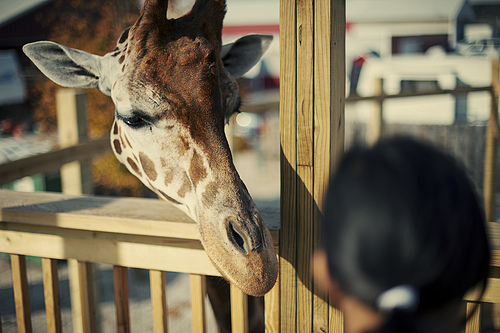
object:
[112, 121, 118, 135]
spot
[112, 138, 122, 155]
spot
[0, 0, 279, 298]
giraffe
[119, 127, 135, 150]
spot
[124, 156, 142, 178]
spot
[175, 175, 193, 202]
spot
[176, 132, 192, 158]
spot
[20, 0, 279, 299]
giraffe head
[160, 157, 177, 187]
brown spot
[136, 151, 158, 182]
brown spot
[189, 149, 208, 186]
brown spot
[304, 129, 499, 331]
person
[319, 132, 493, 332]
black hair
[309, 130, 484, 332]
person's ponytail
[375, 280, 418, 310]
ponytail holder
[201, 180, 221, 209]
brown spots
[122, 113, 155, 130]
giraffe eye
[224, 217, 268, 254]
giraffe nose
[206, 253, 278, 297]
mouth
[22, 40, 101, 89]
ear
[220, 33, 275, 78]
ear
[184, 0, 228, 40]
horn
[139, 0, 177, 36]
horn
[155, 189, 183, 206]
spots